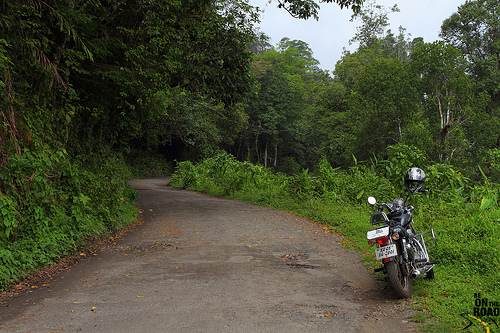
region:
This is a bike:
[339, 150, 456, 330]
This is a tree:
[445, 68, 473, 165]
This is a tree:
[434, 60, 445, 162]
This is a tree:
[385, 54, 413, 171]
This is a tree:
[267, 76, 304, 210]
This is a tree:
[260, 62, 270, 196]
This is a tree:
[242, 85, 257, 187]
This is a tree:
[232, 80, 244, 179]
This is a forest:
[270, 26, 498, 193]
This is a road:
[2, 153, 402, 330]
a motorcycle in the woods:
[361, 163, 448, 295]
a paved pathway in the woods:
[0, 160, 417, 332]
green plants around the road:
[0, 2, 496, 319]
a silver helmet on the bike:
[399, 165, 437, 190]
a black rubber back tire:
[385, 249, 412, 306]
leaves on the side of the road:
[2, 200, 394, 323]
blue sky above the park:
[215, 1, 490, 73]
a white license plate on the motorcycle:
[370, 238, 405, 262]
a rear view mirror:
[366, 190, 379, 207]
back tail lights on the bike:
[372, 235, 394, 249]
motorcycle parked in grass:
[365, 168, 446, 298]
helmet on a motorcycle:
[401, 165, 423, 193]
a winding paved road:
[0, 175, 407, 332]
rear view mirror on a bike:
[365, 195, 378, 205]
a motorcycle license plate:
[373, 244, 398, 258]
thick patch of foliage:
[1, 0, 259, 287]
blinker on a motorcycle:
[391, 232, 399, 240]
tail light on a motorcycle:
[375, 236, 389, 243]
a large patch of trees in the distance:
[235, 3, 499, 201]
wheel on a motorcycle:
[384, 255, 412, 302]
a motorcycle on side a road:
[358, 161, 439, 307]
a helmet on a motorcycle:
[401, 158, 428, 197]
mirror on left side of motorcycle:
[361, 191, 386, 209]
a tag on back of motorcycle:
[369, 240, 400, 261]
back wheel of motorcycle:
[378, 249, 414, 305]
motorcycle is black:
[358, 156, 443, 301]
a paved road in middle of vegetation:
[84, 175, 358, 324]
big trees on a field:
[1, 3, 491, 160]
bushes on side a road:
[166, 139, 391, 196]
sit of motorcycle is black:
[369, 204, 415, 227]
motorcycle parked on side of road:
[352, 176, 449, 296]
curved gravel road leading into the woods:
[52, 133, 385, 323]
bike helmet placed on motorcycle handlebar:
[400, 166, 430, 198]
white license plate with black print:
[372, 242, 397, 259]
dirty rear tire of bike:
[385, 263, 410, 297]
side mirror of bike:
[365, 195, 375, 205]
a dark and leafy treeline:
[5, 3, 422, 178]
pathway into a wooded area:
[48, 128, 341, 323]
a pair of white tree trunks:
[436, 99, 449, 130]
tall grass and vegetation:
[444, 168, 496, 249]